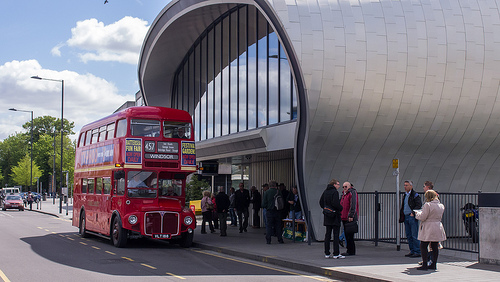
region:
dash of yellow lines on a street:
[1, 205, 190, 278]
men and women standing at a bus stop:
[314, 154, 449, 272]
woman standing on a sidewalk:
[406, 189, 446, 269]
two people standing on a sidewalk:
[317, 178, 362, 260]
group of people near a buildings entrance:
[199, 165, 302, 245]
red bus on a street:
[69, 104, 201, 244]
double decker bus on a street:
[70, 107, 200, 248]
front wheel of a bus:
[104, 208, 125, 244]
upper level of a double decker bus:
[70, 103, 199, 171]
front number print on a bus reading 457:
[143, 139, 157, 151]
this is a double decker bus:
[53, 68, 223, 280]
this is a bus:
[58, 78, 240, 275]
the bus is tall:
[53, 48, 258, 271]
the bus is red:
[66, 96, 213, 261]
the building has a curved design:
[120, 2, 499, 275]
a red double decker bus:
[32, 70, 236, 270]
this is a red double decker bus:
[60, 83, 282, 258]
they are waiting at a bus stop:
[227, 130, 454, 276]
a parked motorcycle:
[457, 185, 491, 251]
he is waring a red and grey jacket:
[328, 167, 375, 263]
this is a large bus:
[71, 68, 262, 265]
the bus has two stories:
[33, 130, 236, 250]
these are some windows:
[104, 180, 181, 203]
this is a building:
[279, 59, 341, 212]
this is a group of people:
[302, 187, 407, 274]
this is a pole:
[378, 164, 427, 210]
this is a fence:
[348, 172, 433, 259]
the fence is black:
[373, 151, 408, 250]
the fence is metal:
[333, 201, 448, 274]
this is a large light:
[19, 98, 72, 120]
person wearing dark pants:
[417, 194, 442, 271]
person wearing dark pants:
[401, 182, 423, 259]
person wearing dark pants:
[339, 181, 359, 258]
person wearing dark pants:
[321, 182, 342, 259]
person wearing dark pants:
[263, 179, 287, 244]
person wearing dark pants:
[251, 183, 264, 231]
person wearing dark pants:
[236, 182, 247, 234]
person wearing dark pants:
[213, 187, 233, 237]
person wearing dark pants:
[198, 192, 216, 238]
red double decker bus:
[73, 116, 198, 245]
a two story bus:
[44, 93, 213, 250]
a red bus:
[55, 94, 208, 246]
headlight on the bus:
[123, 206, 141, 223]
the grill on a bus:
[141, 210, 183, 240]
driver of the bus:
[127, 170, 149, 195]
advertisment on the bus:
[121, 133, 146, 163]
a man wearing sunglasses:
[343, 175, 363, 259]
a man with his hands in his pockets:
[395, 177, 421, 258]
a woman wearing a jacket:
[408, 189, 445, 264]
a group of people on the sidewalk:
[195, 178, 296, 241]